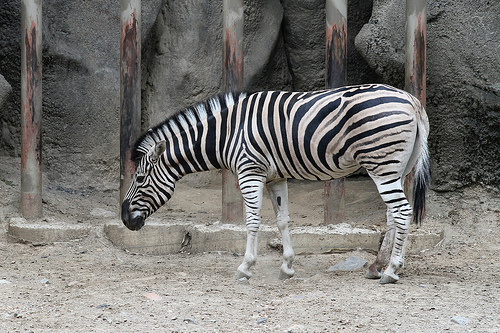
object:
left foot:
[380, 267, 404, 283]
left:
[151, 140, 168, 160]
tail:
[412, 112, 430, 227]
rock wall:
[430, 1, 499, 104]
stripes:
[173, 119, 387, 154]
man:
[81, 5, 222, 89]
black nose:
[119, 210, 130, 228]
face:
[127, 161, 160, 207]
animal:
[118, 82, 434, 284]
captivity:
[3, 1, 494, 331]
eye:
[136, 175, 147, 183]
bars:
[19, 0, 45, 222]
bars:
[116, 2, 147, 213]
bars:
[221, 0, 247, 223]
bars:
[324, 0, 346, 229]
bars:
[406, 0, 428, 101]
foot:
[232, 264, 257, 281]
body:
[225, 85, 402, 191]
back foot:
[379, 266, 400, 284]